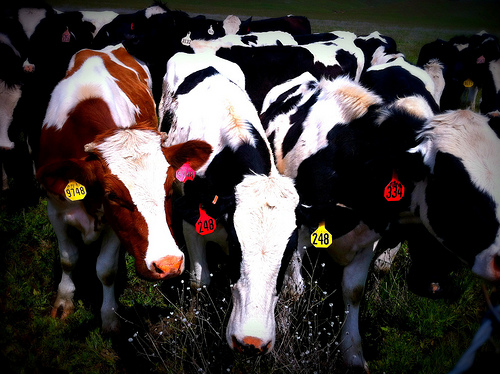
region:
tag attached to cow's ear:
[56, 173, 87, 213]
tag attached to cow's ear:
[158, 136, 222, 197]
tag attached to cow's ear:
[171, 194, 231, 239]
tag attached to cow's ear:
[305, 195, 340, 253]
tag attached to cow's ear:
[372, 165, 404, 218]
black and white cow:
[178, 110, 252, 280]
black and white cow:
[258, 37, 458, 254]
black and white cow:
[149, 35, 280, 305]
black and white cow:
[189, 14, 411, 104]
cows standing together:
[26, 2, 496, 335]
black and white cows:
[15, 14, 499, 303]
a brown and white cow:
[25, 7, 367, 365]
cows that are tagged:
[29, 14, 497, 349]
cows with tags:
[19, 4, 464, 371]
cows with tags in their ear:
[42, 25, 497, 323]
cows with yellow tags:
[7, 11, 479, 367]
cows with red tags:
[23, 28, 493, 349]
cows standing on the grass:
[21, 20, 496, 357]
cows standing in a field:
[41, 14, 498, 333]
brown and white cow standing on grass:
[40, 40, 181, 327]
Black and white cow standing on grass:
[160, 45, 290, 355]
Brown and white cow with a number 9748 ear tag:
[35, 130, 210, 285]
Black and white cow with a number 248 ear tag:
[176, 150, 297, 355]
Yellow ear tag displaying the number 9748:
[35, 155, 90, 205]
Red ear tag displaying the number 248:
[181, 185, 221, 235]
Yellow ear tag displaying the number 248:
[302, 210, 332, 247]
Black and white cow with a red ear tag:
[296, 80, 491, 265]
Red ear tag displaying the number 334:
[356, 145, 411, 200]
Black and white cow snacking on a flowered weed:
[156, 172, 346, 364]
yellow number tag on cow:
[59, 180, 101, 202]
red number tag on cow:
[193, 204, 224, 237]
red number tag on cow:
[172, 157, 202, 180]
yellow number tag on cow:
[308, 227, 338, 252]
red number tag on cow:
[383, 165, 410, 202]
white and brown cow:
[31, 37, 168, 319]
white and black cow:
[166, 50, 303, 359]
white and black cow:
[276, 49, 498, 332]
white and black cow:
[237, 28, 399, 90]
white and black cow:
[31, 8, 201, 72]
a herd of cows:
[4, 5, 499, 369]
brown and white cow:
[29, 45, 192, 334]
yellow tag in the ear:
[304, 216, 336, 246]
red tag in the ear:
[376, 168, 411, 209]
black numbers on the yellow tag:
[64, 181, 89, 203]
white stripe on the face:
[105, 138, 189, 269]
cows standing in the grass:
[0, 1, 495, 371]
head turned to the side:
[387, 103, 499, 292]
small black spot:
[304, 77, 319, 88]